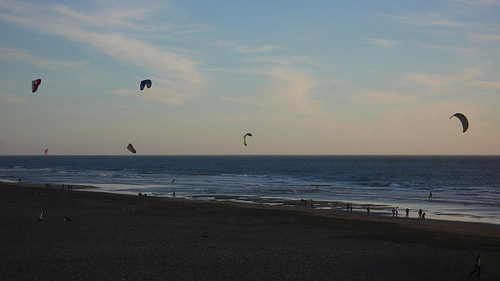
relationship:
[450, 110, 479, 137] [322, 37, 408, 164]
kite in air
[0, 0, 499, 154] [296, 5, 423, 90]
clouds in sky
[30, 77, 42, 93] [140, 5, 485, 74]
kite is in sky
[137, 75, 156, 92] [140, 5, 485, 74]
kite is in sky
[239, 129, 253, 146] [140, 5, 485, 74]
kite is in sky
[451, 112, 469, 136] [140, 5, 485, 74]
kite is in sky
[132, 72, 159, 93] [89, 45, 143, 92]
kite is in sky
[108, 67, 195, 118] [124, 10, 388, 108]
kite is in sky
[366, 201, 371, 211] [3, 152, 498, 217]
person is in water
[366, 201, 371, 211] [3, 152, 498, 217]
person is near water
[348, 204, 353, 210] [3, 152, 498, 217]
person is near water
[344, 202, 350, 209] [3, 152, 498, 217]
person is near water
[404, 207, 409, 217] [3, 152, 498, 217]
person is near water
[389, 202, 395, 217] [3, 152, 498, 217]
person is near water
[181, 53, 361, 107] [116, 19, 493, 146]
clouds is in sky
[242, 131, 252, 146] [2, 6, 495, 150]
kite is in sky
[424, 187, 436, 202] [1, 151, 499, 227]
person is in ocean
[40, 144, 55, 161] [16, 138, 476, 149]
kite is in horizon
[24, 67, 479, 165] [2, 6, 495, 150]
kites in sky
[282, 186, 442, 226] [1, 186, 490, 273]
people in beach